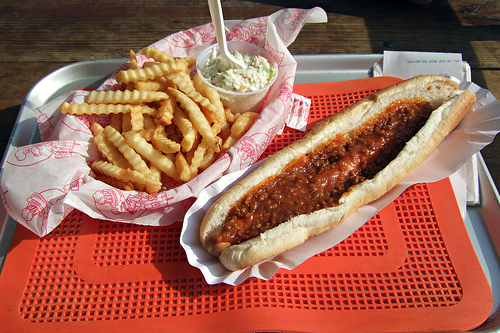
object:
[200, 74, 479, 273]
hotdog bun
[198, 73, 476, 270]
food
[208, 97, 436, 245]
hot chili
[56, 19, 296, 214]
basket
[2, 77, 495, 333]
mat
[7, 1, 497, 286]
food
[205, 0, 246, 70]
fork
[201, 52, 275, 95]
salt packet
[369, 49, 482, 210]
napkins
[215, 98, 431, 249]
chili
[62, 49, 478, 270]
food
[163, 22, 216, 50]
pattern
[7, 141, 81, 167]
pattern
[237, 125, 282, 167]
pattern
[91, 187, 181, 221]
pattern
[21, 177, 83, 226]
pattern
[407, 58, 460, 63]
black text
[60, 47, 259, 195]
french fry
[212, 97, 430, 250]
hot dog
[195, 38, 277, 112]
container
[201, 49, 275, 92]
cole slaw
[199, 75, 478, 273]
bun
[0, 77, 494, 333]
place mat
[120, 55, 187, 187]
cloudy sky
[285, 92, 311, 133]
packet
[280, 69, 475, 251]
food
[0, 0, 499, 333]
picnic table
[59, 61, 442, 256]
food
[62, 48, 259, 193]
fry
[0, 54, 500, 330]
tray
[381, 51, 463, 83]
receipt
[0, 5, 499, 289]
paper